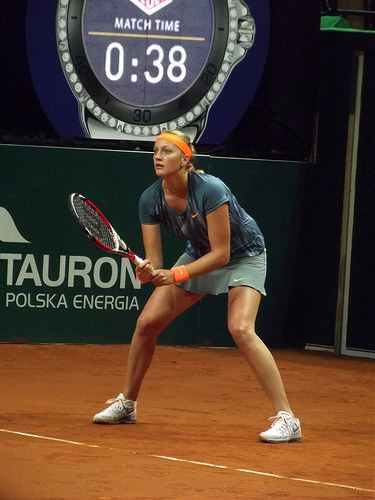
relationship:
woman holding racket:
[94, 130, 305, 440] [70, 189, 141, 285]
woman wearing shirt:
[94, 130, 305, 440] [132, 175, 277, 260]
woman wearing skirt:
[94, 130, 305, 440] [167, 254, 269, 298]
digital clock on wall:
[24, 5, 274, 144] [12, 3, 345, 343]